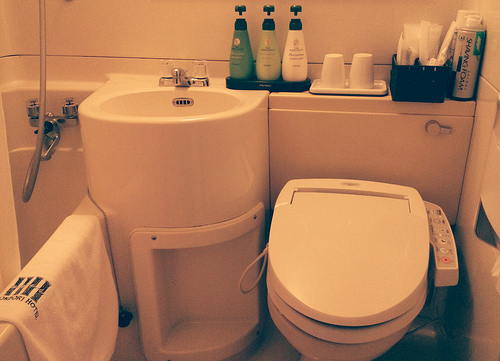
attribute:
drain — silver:
[172, 95, 194, 108]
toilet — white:
[274, 185, 421, 310]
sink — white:
[94, 75, 271, 168]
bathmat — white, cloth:
[3, 216, 120, 360]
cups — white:
[317, 48, 383, 95]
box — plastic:
[382, 44, 471, 119]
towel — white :
[14, 227, 153, 338]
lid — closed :
[270, 178, 434, 307]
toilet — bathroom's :
[264, 87, 474, 331]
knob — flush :
[422, 120, 454, 141]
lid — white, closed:
[268, 189, 429, 329]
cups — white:
[317, 49, 373, 89]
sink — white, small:
[76, 70, 275, 350]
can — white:
[447, 16, 484, 93]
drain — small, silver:
[172, 95, 192, 107]